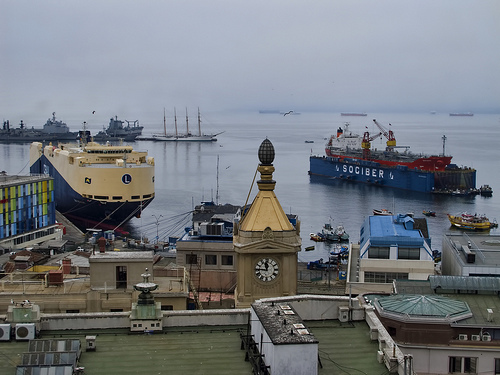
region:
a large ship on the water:
[303, 110, 483, 207]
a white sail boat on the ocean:
[147, 107, 223, 151]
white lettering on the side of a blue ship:
[331, 161, 388, 176]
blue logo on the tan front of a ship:
[121, 173, 133, 183]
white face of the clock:
[251, 258, 281, 279]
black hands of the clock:
[258, 258, 270, 275]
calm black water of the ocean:
[173, 150, 203, 183]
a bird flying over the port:
[277, 106, 299, 123]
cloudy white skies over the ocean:
[206, 33, 328, 90]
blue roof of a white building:
[366, 212, 426, 251]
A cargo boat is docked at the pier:
[14, 120, 161, 235]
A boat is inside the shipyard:
[300, 103, 488, 203]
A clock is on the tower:
[233, 231, 300, 300]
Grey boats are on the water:
[0, 103, 157, 143]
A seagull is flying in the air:
[277, 104, 297, 121]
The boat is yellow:
[435, 202, 490, 231]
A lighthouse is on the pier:
[230, 130, 297, 235]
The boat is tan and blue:
[26, 120, 163, 227]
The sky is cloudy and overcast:
[47, 23, 451, 108]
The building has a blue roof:
[356, 207, 428, 277]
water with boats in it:
[8, 98, 489, 228]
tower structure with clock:
[229, 136, 306, 292]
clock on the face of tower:
[256, 263, 283, 283]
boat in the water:
[305, 115, 490, 215]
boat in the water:
[151, 105, 231, 154]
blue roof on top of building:
[365, 207, 420, 242]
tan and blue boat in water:
[31, 135, 157, 213]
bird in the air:
[278, 106, 299, 122]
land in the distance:
[246, 98, 499, 113]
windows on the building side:
[366, 247, 421, 257]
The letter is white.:
[338, 162, 349, 176]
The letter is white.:
[346, 163, 355, 175]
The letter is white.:
[351, 164, 361, 176]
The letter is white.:
[358, 165, 365, 177]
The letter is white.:
[363, 165, 372, 177]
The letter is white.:
[370, 166, 380, 178]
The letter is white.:
[375, 167, 386, 179]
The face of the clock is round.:
[251, 255, 281, 287]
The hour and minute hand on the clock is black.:
[245, 253, 286, 285]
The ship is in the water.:
[1, 97, 96, 152]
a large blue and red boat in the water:
[299, 124, 479, 206]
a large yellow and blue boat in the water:
[34, 107, 166, 244]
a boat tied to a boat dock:
[38, 126, 145, 256]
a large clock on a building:
[246, 252, 288, 296]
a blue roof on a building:
[357, 206, 432, 264]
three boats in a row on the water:
[6, 88, 212, 155]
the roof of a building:
[0, 296, 297, 373]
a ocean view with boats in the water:
[171, 73, 481, 186]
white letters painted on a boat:
[337, 159, 392, 179]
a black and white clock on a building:
[245, 245, 285, 287]